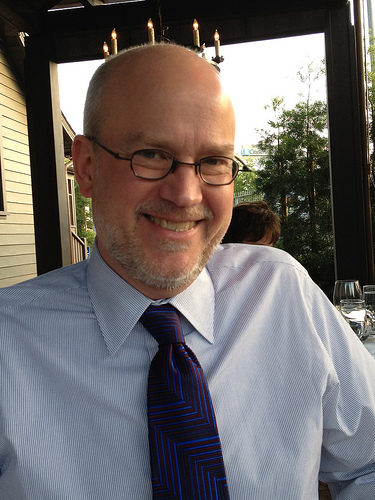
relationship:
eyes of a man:
[143, 147, 225, 176] [11, 39, 371, 500]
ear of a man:
[68, 132, 101, 199] [11, 39, 371, 500]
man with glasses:
[11, 39, 371, 500] [90, 138, 249, 196]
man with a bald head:
[11, 39, 371, 500] [92, 46, 229, 117]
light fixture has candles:
[88, 8, 229, 75] [101, 22, 226, 58]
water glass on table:
[324, 275, 360, 320] [357, 329, 375, 360]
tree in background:
[260, 98, 331, 296] [52, 29, 338, 307]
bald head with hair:
[92, 46, 229, 117] [80, 60, 122, 141]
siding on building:
[0, 65, 41, 281] [4, 3, 105, 290]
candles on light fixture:
[101, 22, 226, 58] [88, 8, 229, 75]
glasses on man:
[90, 138, 249, 196] [11, 39, 371, 500]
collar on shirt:
[90, 237, 219, 353] [4, 248, 371, 499]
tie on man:
[138, 308, 232, 500] [11, 39, 371, 500]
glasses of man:
[90, 138, 249, 196] [11, 39, 371, 500]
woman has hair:
[225, 195, 279, 256] [232, 198, 280, 236]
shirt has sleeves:
[4, 248, 371, 499] [327, 342, 374, 500]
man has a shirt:
[11, 39, 371, 500] [4, 248, 371, 499]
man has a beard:
[11, 39, 371, 500] [84, 175, 238, 287]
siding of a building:
[0, 65, 41, 281] [4, 3, 105, 290]